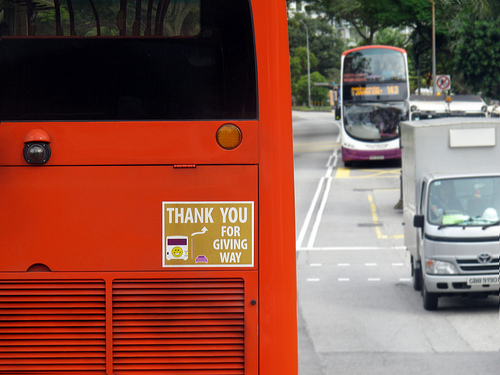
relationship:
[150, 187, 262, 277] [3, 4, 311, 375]
sign on bus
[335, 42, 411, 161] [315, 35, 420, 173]
front of bus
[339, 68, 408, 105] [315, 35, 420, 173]
light on bus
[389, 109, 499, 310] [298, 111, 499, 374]
truck in road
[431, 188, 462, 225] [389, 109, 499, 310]
person in truck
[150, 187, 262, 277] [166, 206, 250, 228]
sign has white letters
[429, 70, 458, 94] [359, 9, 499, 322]
sign on right side of street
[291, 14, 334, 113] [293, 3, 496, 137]
tree in distance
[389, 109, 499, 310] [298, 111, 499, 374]
truck on road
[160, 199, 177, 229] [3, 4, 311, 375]
t on bus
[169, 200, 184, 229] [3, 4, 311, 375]
h on bus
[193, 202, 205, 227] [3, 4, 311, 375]
n on bus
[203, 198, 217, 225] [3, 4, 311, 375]
k on bus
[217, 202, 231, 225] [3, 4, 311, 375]
y on bus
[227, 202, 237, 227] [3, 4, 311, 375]
o on bus